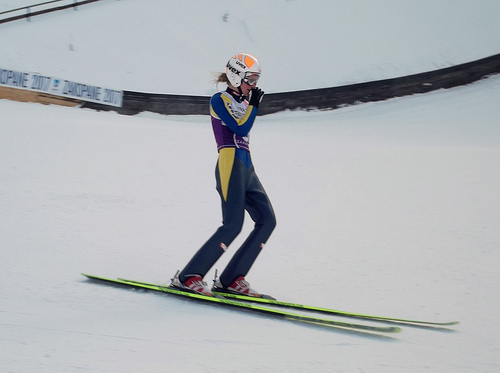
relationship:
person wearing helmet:
[166, 49, 280, 300] [222, 49, 265, 92]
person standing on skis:
[166, 49, 280, 300] [77, 267, 462, 337]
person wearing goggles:
[166, 49, 280, 300] [240, 73, 260, 91]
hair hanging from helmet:
[210, 70, 229, 91] [222, 49, 265, 92]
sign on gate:
[1, 65, 128, 112] [0, 0, 499, 122]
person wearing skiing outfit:
[166, 49, 280, 300] [174, 87, 282, 288]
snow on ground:
[1, 1, 500, 369] [1, 0, 500, 369]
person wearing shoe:
[166, 49, 280, 300] [173, 269, 217, 300]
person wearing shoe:
[166, 49, 280, 300] [215, 271, 262, 299]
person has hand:
[166, 49, 280, 300] [246, 83, 267, 111]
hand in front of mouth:
[246, 83, 267, 111] [244, 84, 252, 96]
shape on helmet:
[228, 51, 260, 73] [222, 49, 265, 92]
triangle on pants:
[216, 145, 238, 207] [174, 144, 280, 290]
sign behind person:
[1, 65, 128, 112] [166, 49, 280, 300]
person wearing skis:
[166, 49, 280, 300] [77, 267, 462, 337]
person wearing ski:
[166, 49, 280, 300] [77, 268, 405, 338]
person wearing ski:
[166, 49, 280, 300] [114, 272, 464, 330]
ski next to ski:
[77, 268, 405, 338] [114, 272, 464, 330]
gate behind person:
[0, 0, 499, 122] [166, 49, 280, 300]